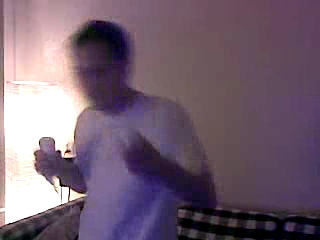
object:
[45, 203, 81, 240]
cat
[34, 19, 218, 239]
man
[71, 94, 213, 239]
shirt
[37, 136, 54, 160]
remote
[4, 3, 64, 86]
window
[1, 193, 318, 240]
sofa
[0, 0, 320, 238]
background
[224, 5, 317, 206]
wall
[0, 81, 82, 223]
lamp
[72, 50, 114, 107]
face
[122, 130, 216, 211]
arm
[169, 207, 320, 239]
pillow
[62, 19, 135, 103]
head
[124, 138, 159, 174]
figers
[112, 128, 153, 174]
had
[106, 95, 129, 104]
eck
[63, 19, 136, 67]
hair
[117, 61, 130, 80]
ear